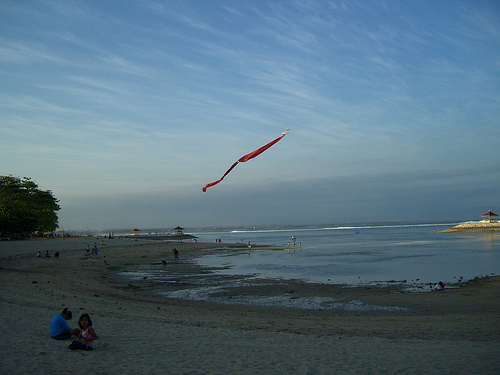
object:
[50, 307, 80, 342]
person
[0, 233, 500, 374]
beach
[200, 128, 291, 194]
kite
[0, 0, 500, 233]
sky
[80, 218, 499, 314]
water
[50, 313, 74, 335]
shirt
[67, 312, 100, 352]
person